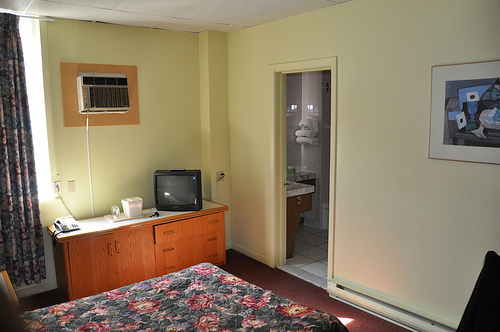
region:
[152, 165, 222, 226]
the TV is black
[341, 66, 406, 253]
the wall is yellow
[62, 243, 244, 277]
the drawer is brown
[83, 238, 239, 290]
the drawer is made of wood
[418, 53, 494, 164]
the frame is on the wall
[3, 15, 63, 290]
the curtain is closed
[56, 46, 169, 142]
the AC is on the wall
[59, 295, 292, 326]
the bed sheet is printed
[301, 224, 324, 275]
the bathroom is tiled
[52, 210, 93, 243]
the phone is on the drawer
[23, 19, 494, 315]
This picture is taken indoors.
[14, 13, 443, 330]
This is a picture of a hotel room.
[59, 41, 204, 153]
A wall air conditioning unit hangs on a wall.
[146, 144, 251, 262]
A T.V. is on a stand.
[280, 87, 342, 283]
There is a bathroom attached to the bedroom.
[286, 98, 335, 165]
Towels are on the the wall of the bathroom.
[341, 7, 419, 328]
The walls are light yellow in color.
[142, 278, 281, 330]
The blanket on the bed is floral in style.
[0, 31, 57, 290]
The curtain style matches the style of the blanket.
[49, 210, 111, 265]
A telephone is on the stand.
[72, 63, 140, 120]
air conditioner propped into the wall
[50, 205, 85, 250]
white corded telephone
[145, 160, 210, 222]
small black television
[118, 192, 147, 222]
white ice container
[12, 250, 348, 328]
floral bedspread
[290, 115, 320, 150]
white bathroom towels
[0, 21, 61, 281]
floral window curtains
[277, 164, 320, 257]
bathroom sink and counter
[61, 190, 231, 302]
light wooden dresser with white top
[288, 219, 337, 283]
white tiled floor with gray grout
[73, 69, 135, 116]
Air conditioner unit mounted on the wall.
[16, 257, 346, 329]
Flower pattered quilt on the bed.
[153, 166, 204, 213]
Small black television on dresser.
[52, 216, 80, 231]
White telephone on dresser below the air conditioner.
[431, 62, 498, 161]
Art frame on the wall.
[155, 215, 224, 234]
Top drawer on the dresser.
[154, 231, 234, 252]
Middle drawer on the dresser.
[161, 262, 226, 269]
Bottom drawer on the dresser.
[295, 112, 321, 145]
White towels on shelf in the bathroom.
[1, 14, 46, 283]
Flower curtains hanging in front of window.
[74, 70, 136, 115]
an air conditioner in the wall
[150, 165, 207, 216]
an old style television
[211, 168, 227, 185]
white colored power outlet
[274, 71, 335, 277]
a motel bathroom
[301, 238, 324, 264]
white tile floor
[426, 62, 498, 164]
artwork hanging on a wall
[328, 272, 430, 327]
white baseboard heater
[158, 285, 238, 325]
floral design bed spread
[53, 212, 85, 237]
white telephone on a dresser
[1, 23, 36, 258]
floral design window curtain